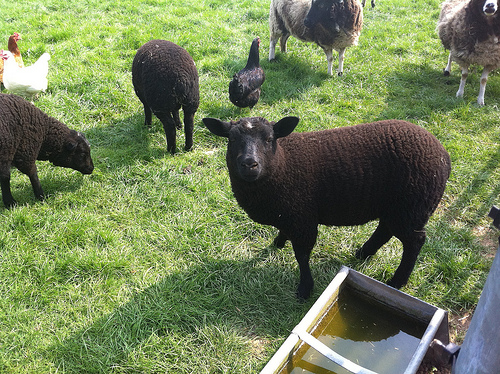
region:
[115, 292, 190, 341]
a shadow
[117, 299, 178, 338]
a shadow on the grass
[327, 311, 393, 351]
liquid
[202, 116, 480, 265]
a sheep standing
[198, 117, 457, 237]
the sheep is black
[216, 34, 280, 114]
a hen standing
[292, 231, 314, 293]
leg of the sheep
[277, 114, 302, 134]
the sheeps ear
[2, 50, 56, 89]
a white hen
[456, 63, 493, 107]
legs on an animal is white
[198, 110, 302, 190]
a sheep seems mesmerized by the camera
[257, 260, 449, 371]
this water does not look very inviting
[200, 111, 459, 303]
a black sheep of the family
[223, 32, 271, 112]
a black chicken wanders through the sheep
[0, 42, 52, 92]
a white chicken mingles with the sheep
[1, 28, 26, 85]
this chicken is red and yellow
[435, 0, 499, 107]
this sheep has really long wool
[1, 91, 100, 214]
this sheep is doing a little grazing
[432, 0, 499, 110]
another sheep seems to have spotted the camera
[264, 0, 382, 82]
this sheep is brown and white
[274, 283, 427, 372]
the murky water in the water bin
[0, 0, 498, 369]
the lush green grass under the animals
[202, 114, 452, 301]
the black sheep near the water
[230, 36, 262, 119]
the black chicken on the grass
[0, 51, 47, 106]
the white chicken on the grass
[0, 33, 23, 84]
the brown chicken on the grass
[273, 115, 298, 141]
the ear on the black sheep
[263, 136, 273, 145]
the eye on the black sheep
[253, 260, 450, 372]
the bin filled with murky water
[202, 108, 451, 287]
black sheep looking at photographer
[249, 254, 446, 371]
water trough with greenish water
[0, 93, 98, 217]
black sheep grazing grass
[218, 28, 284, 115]
black chicken turned away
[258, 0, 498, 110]
pair of light colored sheep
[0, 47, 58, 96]
white chicken in profile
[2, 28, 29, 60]
red headed chicken in profile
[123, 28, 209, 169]
black sheep turned away grazing grass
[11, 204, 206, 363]
long grass covered field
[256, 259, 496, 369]
fence the water trough is attached to